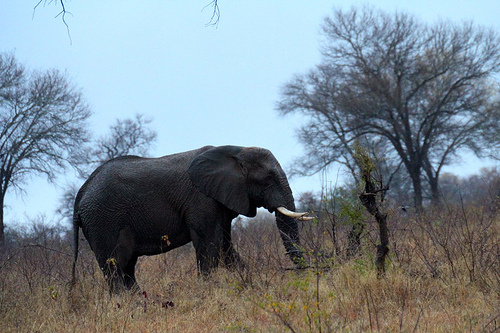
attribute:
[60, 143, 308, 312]
elephant — wrinkled, in wild, large, male, grey, black, walking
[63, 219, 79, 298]
tail — long, black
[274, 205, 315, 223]
tusks — sharp, white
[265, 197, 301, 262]
trunk — hanging, black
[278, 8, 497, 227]
trees — bare, branched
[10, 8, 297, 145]
sky — pale, blue, clear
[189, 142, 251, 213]
ears — big, large, black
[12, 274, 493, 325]
grass — dry, dead, brown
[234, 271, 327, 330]
flowers — small, yellow